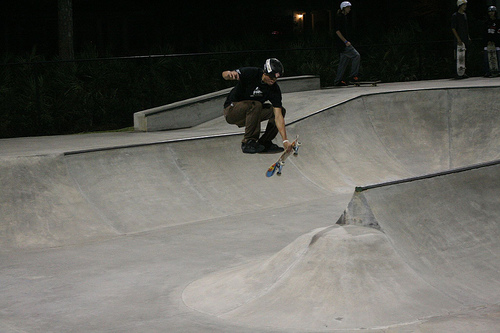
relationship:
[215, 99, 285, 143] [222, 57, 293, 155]
pants worn by man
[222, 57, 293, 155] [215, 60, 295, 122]
man wearing shirt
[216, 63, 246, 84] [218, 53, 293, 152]
arm on man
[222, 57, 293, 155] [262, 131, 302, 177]
man on skate board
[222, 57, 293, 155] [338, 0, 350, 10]
man wearing helmet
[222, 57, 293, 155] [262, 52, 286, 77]
man wearing helmet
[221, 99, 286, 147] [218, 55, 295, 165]
pants on man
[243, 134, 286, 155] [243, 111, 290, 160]
shoes on man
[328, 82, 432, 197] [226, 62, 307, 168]
ramp behind man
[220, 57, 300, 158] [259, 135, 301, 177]
man with skateboard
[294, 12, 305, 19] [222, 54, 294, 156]
light behind man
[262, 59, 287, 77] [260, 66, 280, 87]
helmet on head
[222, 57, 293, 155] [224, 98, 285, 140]
man wearing pants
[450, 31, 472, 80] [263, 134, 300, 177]
person holding skateboard